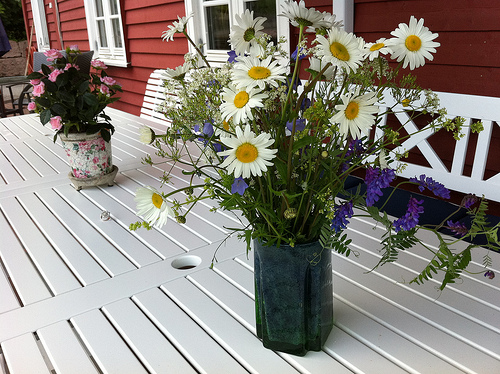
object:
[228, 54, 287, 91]
daisies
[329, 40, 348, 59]
center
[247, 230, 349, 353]
vase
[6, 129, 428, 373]
table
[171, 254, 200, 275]
hole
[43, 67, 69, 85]
roses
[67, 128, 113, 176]
planter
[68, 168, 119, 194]
stand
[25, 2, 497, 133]
wall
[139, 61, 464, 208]
bench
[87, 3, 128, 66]
window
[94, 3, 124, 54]
panes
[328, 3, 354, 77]
rain gutter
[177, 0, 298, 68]
frame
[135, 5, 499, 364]
bouquet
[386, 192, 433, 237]
flowers